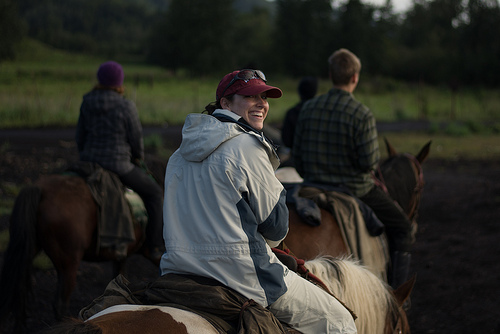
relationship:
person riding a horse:
[73, 60, 161, 261] [0, 161, 169, 325]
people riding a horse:
[152, 67, 366, 334] [283, 137, 434, 288]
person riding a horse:
[280, 75, 320, 158] [80, 257, 412, 332]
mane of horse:
[307, 258, 392, 332] [80, 257, 412, 332]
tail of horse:
[5, 184, 44, 322] [0, 161, 169, 325]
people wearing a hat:
[152, 67, 366, 334] [95, 59, 124, 83]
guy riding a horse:
[290, 48, 414, 290] [272, 166, 427, 273]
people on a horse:
[152, 67, 366, 334] [80, 257, 412, 332]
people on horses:
[77, 50, 384, 270] [8, 44, 432, 332]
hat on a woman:
[95, 63, 125, 91] [77, 62, 167, 237]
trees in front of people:
[1, 0, 499, 87] [152, 67, 366, 334]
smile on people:
[249, 108, 263, 118] [152, 67, 366, 334]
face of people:
[214, 85, 294, 144] [152, 67, 366, 334]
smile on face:
[249, 108, 263, 118] [214, 85, 294, 144]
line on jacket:
[212, 150, 286, 215] [158, 109, 291, 309]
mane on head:
[305, 249, 392, 332] [320, 264, 411, 331]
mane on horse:
[305, 249, 392, 332] [263, 256, 407, 332]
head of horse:
[320, 264, 411, 331] [263, 256, 407, 332]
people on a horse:
[152, 67, 366, 334] [3, 146, 178, 332]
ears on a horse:
[382, 136, 432, 163] [249, 96, 454, 288]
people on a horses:
[152, 67, 366, 334] [10, 155, 180, 315]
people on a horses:
[152, 67, 366, 334] [274, 132, 443, 270]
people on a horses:
[152, 67, 366, 334] [24, 253, 420, 332]